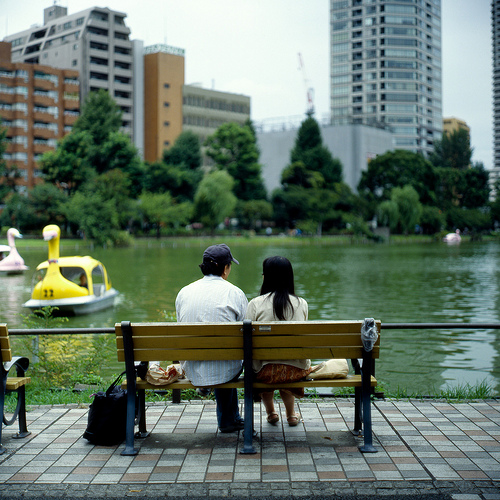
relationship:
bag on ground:
[83, 384, 138, 446] [7, 396, 499, 495]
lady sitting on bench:
[249, 257, 309, 430] [102, 305, 384, 438]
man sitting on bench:
[174, 243, 250, 433] [105, 316, 395, 436]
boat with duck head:
[18, 216, 121, 316] [40, 216, 66, 252]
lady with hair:
[246, 257, 310, 426] [254, 249, 300, 319]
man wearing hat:
[165, 233, 253, 440] [200, 243, 242, 266]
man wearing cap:
[174, 243, 250, 433] [203, 244, 241, 266]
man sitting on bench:
[174, 243, 250, 433] [104, 314, 386, 447]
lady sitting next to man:
[249, 257, 309, 430] [178, 240, 250, 434]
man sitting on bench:
[174, 243, 250, 433] [94, 319, 387, 453]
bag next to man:
[83, 377, 150, 447] [174, 243, 250, 433]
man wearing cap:
[174, 243, 250, 433] [200, 231, 246, 271]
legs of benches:
[252, 393, 312, 424] [110, 309, 389, 458]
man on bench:
[174, 243, 250, 433] [104, 314, 386, 447]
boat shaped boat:
[21, 222, 119, 316] [21, 222, 119, 316]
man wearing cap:
[174, 243, 250, 433] [195, 242, 245, 263]